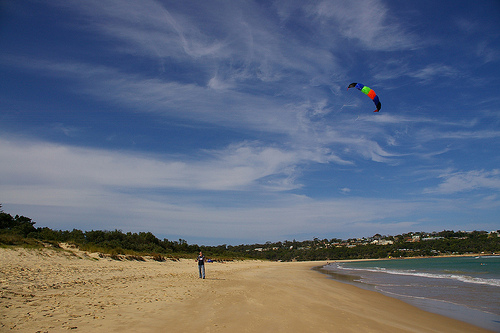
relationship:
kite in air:
[342, 81, 382, 114] [6, 11, 492, 323]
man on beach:
[195, 250, 208, 280] [7, 254, 487, 326]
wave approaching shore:
[321, 255, 497, 300] [2, 258, 489, 329]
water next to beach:
[310, 254, 500, 332] [7, 254, 487, 326]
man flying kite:
[195, 250, 208, 280] [342, 81, 382, 114]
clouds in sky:
[19, 4, 493, 215] [6, 11, 492, 323]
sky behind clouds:
[1, 2, 495, 235] [19, 4, 493, 215]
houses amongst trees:
[239, 226, 499, 258] [0, 208, 500, 266]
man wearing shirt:
[195, 250, 208, 280] [198, 254, 206, 265]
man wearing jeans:
[195, 250, 208, 280] [196, 266, 207, 279]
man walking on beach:
[195, 250, 208, 280] [7, 254, 487, 326]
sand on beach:
[9, 254, 464, 329] [7, 254, 487, 326]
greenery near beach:
[1, 208, 499, 264] [7, 254, 487, 326]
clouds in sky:
[19, 4, 493, 215] [1, 2, 495, 235]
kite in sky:
[345, 77, 389, 106] [1, 2, 495, 235]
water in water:
[331, 237, 500, 318] [310, 254, 500, 332]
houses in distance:
[239, 226, 499, 258] [3, 71, 499, 270]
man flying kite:
[195, 250, 208, 280] [345, 77, 389, 106]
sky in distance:
[1, 2, 495, 235] [3, 71, 499, 270]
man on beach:
[198, 247, 207, 279] [7, 254, 487, 326]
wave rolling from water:
[329, 260, 499, 289] [310, 254, 500, 332]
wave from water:
[329, 260, 499, 289] [310, 254, 500, 332]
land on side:
[4, 249, 462, 329] [7, 2, 394, 321]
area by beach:
[9, 251, 255, 260] [7, 254, 487, 326]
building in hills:
[364, 232, 397, 249] [239, 221, 500, 267]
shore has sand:
[2, 258, 489, 329] [9, 254, 464, 329]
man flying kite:
[198, 247, 207, 279] [345, 77, 389, 106]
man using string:
[198, 247, 207, 279] [208, 89, 353, 264]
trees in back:
[0, 208, 500, 266] [7, 2, 497, 268]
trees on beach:
[0, 208, 500, 266] [7, 254, 487, 326]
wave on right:
[329, 260, 499, 289] [309, 1, 497, 326]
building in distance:
[364, 232, 397, 249] [3, 71, 499, 270]